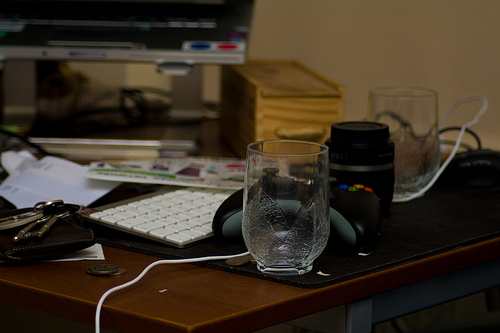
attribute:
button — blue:
[326, 170, 365, 223]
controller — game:
[212, 159, 369, 278]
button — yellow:
[347, 177, 374, 205]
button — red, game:
[336, 173, 365, 203]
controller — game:
[202, 170, 367, 273]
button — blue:
[326, 167, 379, 208]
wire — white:
[59, 255, 149, 306]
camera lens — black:
[324, 112, 403, 192]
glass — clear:
[237, 131, 326, 272]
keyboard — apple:
[99, 197, 199, 246]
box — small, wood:
[227, 66, 319, 145]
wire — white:
[92, 94, 491, 331]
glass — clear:
[367, 83, 442, 204]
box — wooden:
[213, 57, 347, 159]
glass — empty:
[239, 137, 330, 277]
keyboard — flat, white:
[89, 187, 231, 247]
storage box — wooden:
[212, 56, 346, 166]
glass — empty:
[369, 82, 439, 200]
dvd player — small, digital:
[29, 118, 202, 151]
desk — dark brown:
[5, 240, 498, 330]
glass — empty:
[246, 144, 338, 274]